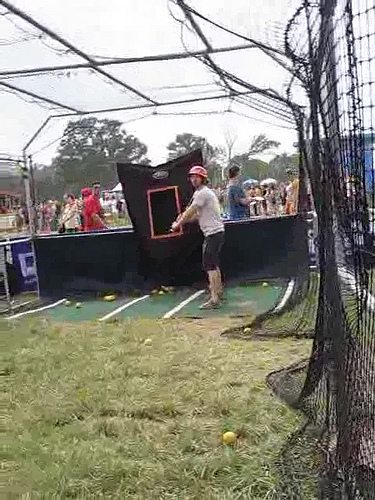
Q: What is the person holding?
A: Bat.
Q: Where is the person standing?
A: Batting cage.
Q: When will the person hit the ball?
A: No indication.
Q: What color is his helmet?
A: Red.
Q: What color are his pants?
A: Black.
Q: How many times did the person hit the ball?
A: No indication.